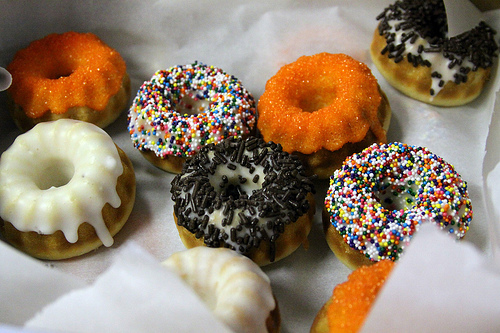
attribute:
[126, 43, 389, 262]
donuts — tasty, different colors, these, mini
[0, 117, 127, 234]
topping — white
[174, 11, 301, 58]
paper — parchment, white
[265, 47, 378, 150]
toppings — white, orange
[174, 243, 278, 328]
doughnut — lemon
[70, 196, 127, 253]
white icing — dripping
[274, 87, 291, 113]
frosting — orange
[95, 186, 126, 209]
frosting — dripping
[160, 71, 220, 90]
sprinkles — these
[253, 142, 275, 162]
sprinkles — chocolate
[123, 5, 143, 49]
nonparells — these